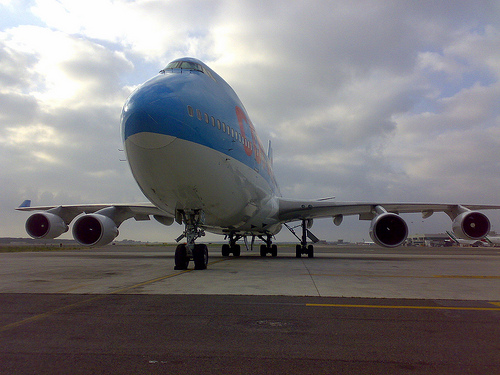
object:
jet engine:
[73, 212, 120, 247]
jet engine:
[24, 207, 63, 241]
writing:
[234, 104, 274, 172]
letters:
[237, 103, 260, 159]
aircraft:
[14, 53, 498, 272]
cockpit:
[160, 56, 217, 82]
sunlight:
[34, 25, 96, 107]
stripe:
[303, 302, 499, 312]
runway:
[0, 235, 498, 372]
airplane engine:
[450, 208, 491, 240]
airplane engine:
[366, 204, 410, 248]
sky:
[0, 0, 500, 221]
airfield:
[2, 240, 497, 375]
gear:
[173, 243, 193, 272]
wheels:
[173, 242, 191, 270]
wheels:
[231, 240, 241, 258]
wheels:
[220, 243, 231, 258]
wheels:
[295, 242, 304, 258]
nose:
[116, 78, 227, 173]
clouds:
[217, 0, 498, 109]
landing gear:
[294, 244, 315, 260]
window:
[196, 108, 202, 121]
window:
[210, 115, 216, 127]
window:
[181, 60, 203, 71]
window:
[165, 60, 179, 69]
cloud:
[24, 1, 175, 57]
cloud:
[3, 36, 139, 98]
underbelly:
[126, 142, 275, 233]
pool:
[144, 355, 173, 367]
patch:
[0, 2, 44, 28]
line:
[301, 300, 500, 312]